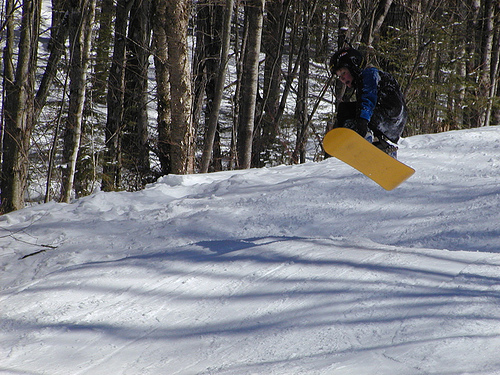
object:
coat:
[355, 65, 409, 144]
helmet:
[329, 48, 367, 76]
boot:
[343, 117, 368, 138]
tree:
[150, 0, 173, 175]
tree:
[201, 0, 236, 172]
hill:
[4, 2, 497, 374]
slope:
[6, 125, 495, 374]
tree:
[153, 0, 192, 175]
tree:
[485, 47, 499, 126]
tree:
[99, 0, 152, 191]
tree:
[29, 1, 78, 130]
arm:
[358, 71, 380, 122]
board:
[322, 127, 416, 192]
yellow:
[321, 127, 415, 190]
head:
[329, 47, 367, 89]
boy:
[319, 47, 408, 160]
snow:
[0, 269, 500, 375]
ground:
[1, 217, 493, 368]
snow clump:
[170, 175, 295, 207]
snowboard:
[322, 127, 416, 191]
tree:
[231, 0, 262, 169]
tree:
[235, 1, 264, 171]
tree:
[60, 1, 95, 201]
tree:
[0, 0, 42, 215]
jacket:
[337, 66, 409, 144]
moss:
[95, 38, 111, 67]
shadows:
[0, 229, 500, 375]